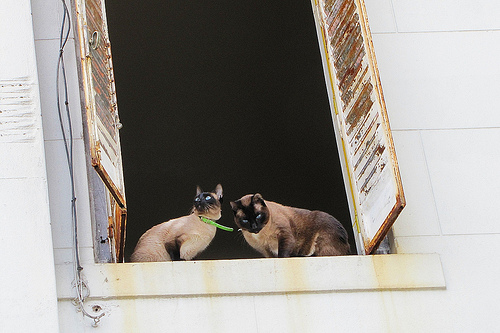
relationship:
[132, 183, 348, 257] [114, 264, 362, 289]
cats sit on ledge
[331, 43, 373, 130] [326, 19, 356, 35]
shutter covered in rust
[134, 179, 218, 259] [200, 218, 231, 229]
cat wearing green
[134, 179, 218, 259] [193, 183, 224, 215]
cat looking up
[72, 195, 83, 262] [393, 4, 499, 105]
lines on building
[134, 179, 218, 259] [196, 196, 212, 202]
cat has blue eyes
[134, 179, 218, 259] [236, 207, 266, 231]
cat has dark face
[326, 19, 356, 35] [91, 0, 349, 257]
rust stains down window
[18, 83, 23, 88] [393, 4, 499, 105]
hole in side of building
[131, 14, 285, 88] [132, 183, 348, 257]
darkness behind cats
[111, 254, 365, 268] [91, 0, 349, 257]
edge of window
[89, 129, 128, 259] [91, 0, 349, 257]
part of window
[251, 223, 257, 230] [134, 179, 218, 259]
nose of cat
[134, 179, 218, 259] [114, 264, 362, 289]
cat on window sill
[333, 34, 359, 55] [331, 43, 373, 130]
rusty white shutter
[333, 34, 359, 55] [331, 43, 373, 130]
rusty window shutter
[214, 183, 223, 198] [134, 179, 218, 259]
ear of cat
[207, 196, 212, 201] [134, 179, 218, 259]
blue eye of cat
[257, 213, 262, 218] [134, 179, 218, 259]
eye of cat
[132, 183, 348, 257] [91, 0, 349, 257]
cats in window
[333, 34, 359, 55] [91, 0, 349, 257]
rusty shutter on window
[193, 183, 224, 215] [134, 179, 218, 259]
head of cat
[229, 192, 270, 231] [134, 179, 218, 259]
head of cat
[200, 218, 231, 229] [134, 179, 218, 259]
green collar on cat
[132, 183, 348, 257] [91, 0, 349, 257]
two cats in window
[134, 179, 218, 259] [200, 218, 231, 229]
cat with green collar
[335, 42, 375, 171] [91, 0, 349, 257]
shutters on window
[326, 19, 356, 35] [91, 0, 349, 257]
rust dripping from window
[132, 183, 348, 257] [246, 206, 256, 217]
cats are beige and black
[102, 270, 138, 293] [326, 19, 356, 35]
wall has rust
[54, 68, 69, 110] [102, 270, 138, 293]
wire hanging on wall